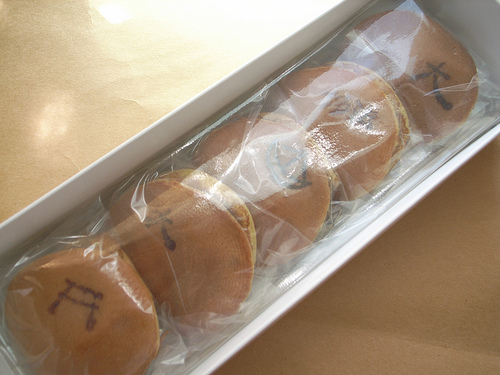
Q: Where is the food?
A: In plastic wrap.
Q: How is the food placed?
A: Wrapped.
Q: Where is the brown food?
A: In packaging.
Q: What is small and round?
A: Piece of food.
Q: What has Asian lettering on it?
A: Food.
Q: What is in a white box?
A: Food.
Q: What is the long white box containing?
A: Food.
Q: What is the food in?
A: Plastic wrapping.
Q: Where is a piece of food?
A: In the box.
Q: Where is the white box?
A: On a table.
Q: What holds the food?
A: A box.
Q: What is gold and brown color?
A: The food.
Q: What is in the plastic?
A: Food.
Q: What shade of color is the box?
A: White.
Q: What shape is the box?
A: Rectangular.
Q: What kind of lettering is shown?
A: Chinese.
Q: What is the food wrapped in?
A: Plastic.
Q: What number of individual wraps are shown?
A: 5.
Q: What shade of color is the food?
A: Brown.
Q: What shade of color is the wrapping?
A: Clear.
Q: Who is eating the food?
A: No One is in the photo.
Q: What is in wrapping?
A: Pancakes.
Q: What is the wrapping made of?
A: Plastic.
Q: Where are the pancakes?
A: In a box.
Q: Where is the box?
A: On a table.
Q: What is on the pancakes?
A: Characters.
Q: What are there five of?
A: Wrapped pancakes.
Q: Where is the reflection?
A: On the plastic and the table.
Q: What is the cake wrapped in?
A: Plastic.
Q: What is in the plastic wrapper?
A: Cake.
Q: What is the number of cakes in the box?
A: Five.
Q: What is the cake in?
A: White box.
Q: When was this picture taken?
A: Daytime.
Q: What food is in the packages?
A: Pancakes.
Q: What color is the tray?
A: White.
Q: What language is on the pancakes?
A: Chinese.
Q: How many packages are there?
A: 5.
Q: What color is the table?
A: Tan.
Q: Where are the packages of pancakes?
A: In tray.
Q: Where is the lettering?
A: On pancakes.